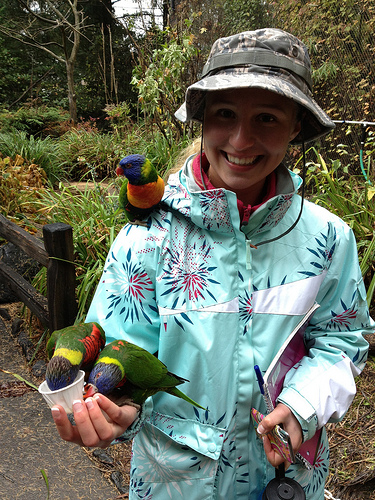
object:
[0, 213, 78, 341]
fence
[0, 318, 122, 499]
trail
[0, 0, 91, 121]
tree